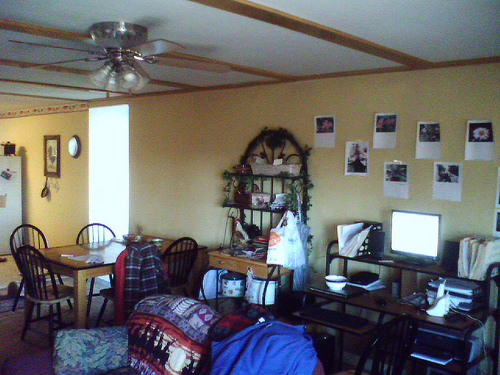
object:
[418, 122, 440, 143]
picture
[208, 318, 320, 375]
garment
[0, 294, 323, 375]
couch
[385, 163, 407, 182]
picture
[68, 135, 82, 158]
clock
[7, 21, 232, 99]
ceiling fan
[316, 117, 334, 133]
picture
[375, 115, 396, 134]
picture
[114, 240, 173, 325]
clothes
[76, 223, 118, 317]
chair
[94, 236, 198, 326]
chair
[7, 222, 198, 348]
set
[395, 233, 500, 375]
printer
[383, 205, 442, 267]
monitor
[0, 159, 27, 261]
refrigerator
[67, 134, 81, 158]
black rim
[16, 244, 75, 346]
chair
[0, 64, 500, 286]
wall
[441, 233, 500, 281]
folders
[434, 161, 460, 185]
picture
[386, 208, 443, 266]
computer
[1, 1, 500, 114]
roof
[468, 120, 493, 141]
picture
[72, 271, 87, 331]
leg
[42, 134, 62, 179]
picture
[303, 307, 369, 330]
keyboard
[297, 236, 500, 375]
desk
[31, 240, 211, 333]
table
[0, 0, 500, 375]
room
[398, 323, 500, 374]
shelf